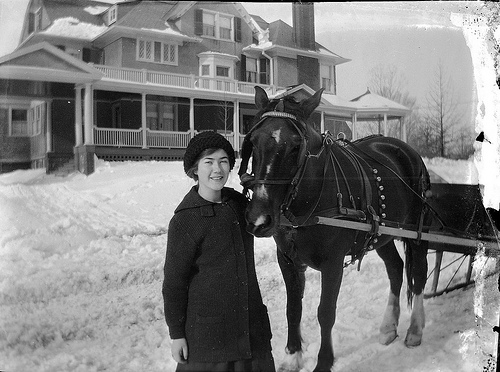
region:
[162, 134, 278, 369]
woman standing next to a horse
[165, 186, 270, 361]
long black sweater on the woman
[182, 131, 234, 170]
black knit beanie on the woman's head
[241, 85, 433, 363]
horse standing in the snow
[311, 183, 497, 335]
sleigh horse is pulling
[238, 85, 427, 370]
horse is pulling a sleigh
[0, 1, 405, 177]
large house in the background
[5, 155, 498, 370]
fresh snow on the ground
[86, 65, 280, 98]
balcony on the house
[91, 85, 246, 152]
front porch of the house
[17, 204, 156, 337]
the snow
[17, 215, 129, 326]
the snow is white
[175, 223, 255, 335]
a black coat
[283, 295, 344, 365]
the horses front legs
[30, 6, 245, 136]
a home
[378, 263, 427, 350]
the horses back legs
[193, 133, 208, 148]
women is wearing a hat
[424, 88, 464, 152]
tree branches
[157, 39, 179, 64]
a window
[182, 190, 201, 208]
a collar on the jacket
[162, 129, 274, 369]
woman outside a house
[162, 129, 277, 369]
woman outside in winter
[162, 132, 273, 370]
woman outside in her hat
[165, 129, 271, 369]
woman outside in her coat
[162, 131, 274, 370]
woman standing by a horse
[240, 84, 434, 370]
horse standing by a woman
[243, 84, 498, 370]
horse pulling a sleigh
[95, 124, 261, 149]
railing on front porch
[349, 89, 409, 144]
gazebo on porch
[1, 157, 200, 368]
snow on the lawn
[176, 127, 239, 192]
the head of a woman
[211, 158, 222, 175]
the nose of a woman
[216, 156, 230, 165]
the eye of a woman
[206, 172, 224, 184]
the mouth of a woman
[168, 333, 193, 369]
the hand of a woman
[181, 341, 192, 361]
the thumb of a woman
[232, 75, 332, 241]
the head of a horse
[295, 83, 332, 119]
the ear of a horse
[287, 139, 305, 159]
the eye of a horse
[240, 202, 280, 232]
the nose of a horse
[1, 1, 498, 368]
the photograph is black and white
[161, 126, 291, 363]
the girl beside the horse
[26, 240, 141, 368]
the snow on the ground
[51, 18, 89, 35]
snow on the roof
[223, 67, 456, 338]
the horse beside the girl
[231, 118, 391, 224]
the bridal on the horse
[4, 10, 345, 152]
the house is large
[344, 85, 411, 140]
the gazebo beside the house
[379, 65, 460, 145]
the trees are bare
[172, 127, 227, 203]
the girl wearing a hat